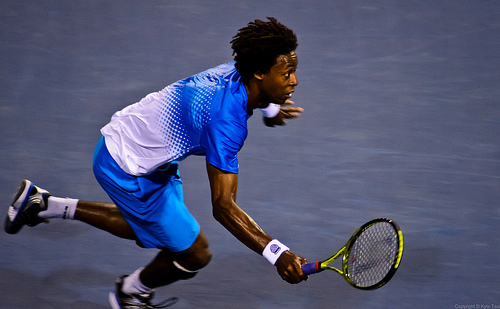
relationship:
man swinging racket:
[3, 15, 309, 308] [300, 217, 405, 291]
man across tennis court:
[3, 15, 309, 308] [3, 2, 500, 309]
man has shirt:
[3, 15, 309, 308] [100, 61, 252, 177]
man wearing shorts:
[3, 15, 309, 308] [91, 134, 201, 253]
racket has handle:
[300, 217, 405, 291] [301, 261, 323, 276]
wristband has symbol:
[262, 238, 291, 266] [269, 243, 283, 254]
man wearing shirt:
[3, 15, 309, 308] [100, 61, 252, 177]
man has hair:
[3, 15, 309, 308] [229, 15, 299, 84]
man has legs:
[3, 15, 309, 308] [54, 179, 213, 288]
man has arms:
[3, 15, 309, 308] [204, 103, 284, 261]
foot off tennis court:
[3, 178, 53, 234] [3, 2, 500, 309]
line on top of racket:
[392, 229, 405, 269] [300, 217, 405, 291]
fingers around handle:
[283, 257, 308, 285] [301, 261, 323, 276]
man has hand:
[3, 15, 309, 308] [276, 252, 308, 285]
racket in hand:
[300, 217, 405, 291] [276, 252, 308, 285]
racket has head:
[300, 217, 405, 291] [343, 218, 403, 292]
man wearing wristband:
[3, 15, 309, 308] [262, 238, 291, 266]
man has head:
[3, 15, 309, 308] [230, 14, 299, 105]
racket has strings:
[300, 217, 405, 291] [348, 222, 396, 287]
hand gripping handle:
[276, 252, 308, 285] [301, 261, 323, 276]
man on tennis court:
[3, 15, 309, 308] [3, 2, 500, 309]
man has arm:
[3, 15, 309, 308] [206, 163, 285, 263]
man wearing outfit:
[3, 15, 309, 308] [92, 61, 249, 252]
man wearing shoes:
[3, 15, 309, 308] [4, 179, 179, 309]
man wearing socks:
[3, 15, 309, 308] [37, 195, 156, 296]